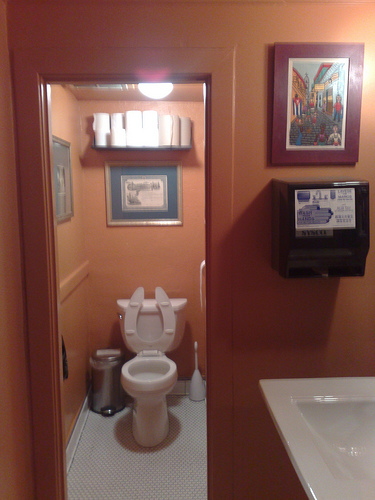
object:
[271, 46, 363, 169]
picture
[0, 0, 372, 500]
wall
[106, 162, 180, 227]
picture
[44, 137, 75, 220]
picture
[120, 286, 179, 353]
seat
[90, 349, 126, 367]
lid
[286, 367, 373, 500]
sink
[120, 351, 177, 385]
bowl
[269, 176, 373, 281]
towel holder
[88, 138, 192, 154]
shelf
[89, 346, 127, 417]
basket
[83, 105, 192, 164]
brush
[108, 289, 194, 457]
toilet bowl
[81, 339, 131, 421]
trash can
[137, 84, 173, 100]
light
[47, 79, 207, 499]
restroom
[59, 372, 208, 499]
floor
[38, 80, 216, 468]
bathroom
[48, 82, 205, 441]
orange wall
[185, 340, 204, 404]
toilet scrubber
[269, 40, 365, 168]
art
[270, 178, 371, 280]
dispenser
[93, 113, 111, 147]
toilet paper